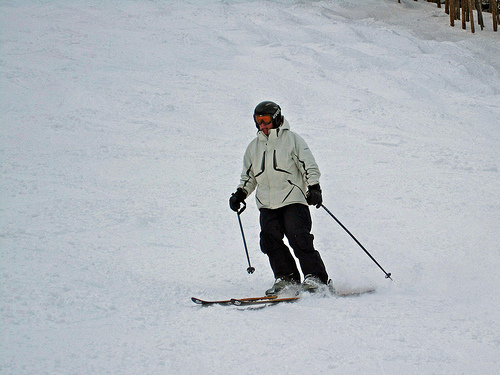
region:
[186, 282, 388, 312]
a pair of skis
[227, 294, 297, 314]
top of the ski hovering over the ground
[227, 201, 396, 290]
a pair of ski poles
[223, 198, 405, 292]
ski poles lifted off the ground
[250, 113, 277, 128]
goggles on the face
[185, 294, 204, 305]
top of the ski is bent up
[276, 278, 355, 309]
snow being kicked up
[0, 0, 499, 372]
white snow on the ground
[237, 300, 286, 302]
A ski on the ice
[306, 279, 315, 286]
The snow shoes on the ski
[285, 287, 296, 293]
Ice flying over the ski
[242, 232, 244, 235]
The shaft of the pole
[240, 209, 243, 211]
The pole wrist wrap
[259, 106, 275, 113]
The skier's helmet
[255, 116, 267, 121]
Skier wearing gogles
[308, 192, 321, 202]
Hand covered in a glove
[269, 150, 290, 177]
black line on jacket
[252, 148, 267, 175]
black line on jacket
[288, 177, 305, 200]
black line on jacket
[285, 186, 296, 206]
black line on jacket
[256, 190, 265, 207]
black line on jacket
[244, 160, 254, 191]
black line on jacket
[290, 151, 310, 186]
black line on jacket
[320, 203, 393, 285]
black colored ski pole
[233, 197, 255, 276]
black colored ski pole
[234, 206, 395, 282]
black colored ski poles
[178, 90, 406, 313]
A person skiing in snow